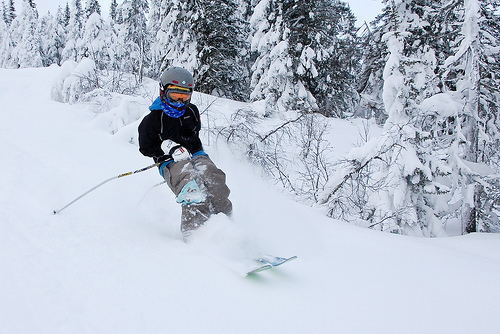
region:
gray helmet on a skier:
[91, 33, 224, 136]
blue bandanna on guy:
[123, 81, 207, 127]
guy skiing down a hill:
[86, 16, 284, 331]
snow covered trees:
[279, 11, 498, 237]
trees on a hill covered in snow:
[252, 15, 444, 279]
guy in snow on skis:
[94, 45, 336, 285]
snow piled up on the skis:
[174, 188, 298, 298]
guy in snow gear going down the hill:
[90, 32, 254, 265]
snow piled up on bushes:
[44, 34, 114, 134]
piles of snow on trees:
[401, 85, 474, 249]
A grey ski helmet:
[152, 62, 202, 96]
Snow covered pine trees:
[172, 0, 337, 103]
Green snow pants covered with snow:
[155, 153, 244, 244]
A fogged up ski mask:
[150, 78, 198, 108]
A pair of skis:
[143, 212, 297, 285]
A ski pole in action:
[46, 142, 197, 225]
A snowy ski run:
[27, 120, 324, 307]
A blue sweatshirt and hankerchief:
[140, 91, 213, 175]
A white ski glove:
[153, 135, 195, 165]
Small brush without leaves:
[234, 107, 329, 187]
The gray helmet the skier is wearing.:
[162, 62, 194, 85]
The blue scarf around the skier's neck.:
[150, 95, 183, 120]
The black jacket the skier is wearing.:
[135, 110, 202, 155]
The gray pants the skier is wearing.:
[160, 155, 235, 215]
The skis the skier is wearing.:
[191, 225, 276, 290]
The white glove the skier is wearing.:
[153, 132, 195, 162]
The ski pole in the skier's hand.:
[42, 147, 176, 199]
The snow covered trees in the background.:
[4, 2, 498, 241]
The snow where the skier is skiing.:
[11, 74, 493, 329]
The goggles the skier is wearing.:
[161, 85, 191, 107]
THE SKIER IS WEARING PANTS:
[156, 145, 237, 241]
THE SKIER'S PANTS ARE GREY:
[153, 145, 234, 239]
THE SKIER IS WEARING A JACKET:
[131, 93, 211, 168]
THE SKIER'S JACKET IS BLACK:
[135, 100, 210, 171]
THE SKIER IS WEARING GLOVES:
[158, 136, 192, 171]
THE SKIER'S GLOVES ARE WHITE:
[158, 135, 193, 167]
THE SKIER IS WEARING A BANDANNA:
[140, 91, 189, 122]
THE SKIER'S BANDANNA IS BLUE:
[148, 93, 193, 125]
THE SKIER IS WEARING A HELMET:
[155, 62, 198, 110]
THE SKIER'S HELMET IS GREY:
[153, 64, 204, 114]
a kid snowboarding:
[95, 52, 331, 290]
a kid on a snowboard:
[94, 47, 325, 323]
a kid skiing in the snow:
[97, 29, 342, 331]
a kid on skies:
[127, 45, 339, 325]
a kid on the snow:
[94, 41, 354, 330]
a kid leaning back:
[105, 7, 332, 312]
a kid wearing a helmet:
[111, 43, 228, 182]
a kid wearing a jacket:
[112, 51, 246, 208]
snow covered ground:
[72, 243, 159, 299]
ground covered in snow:
[53, 241, 186, 322]